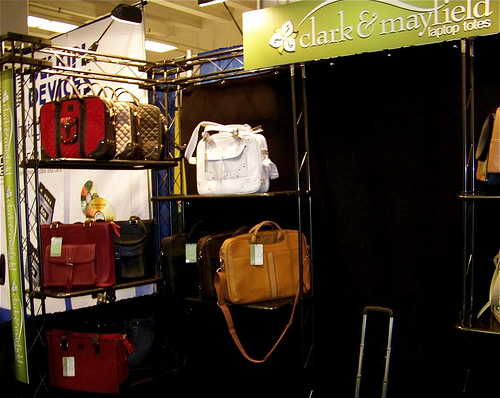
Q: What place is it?
A: It is a store.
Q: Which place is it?
A: It is a store.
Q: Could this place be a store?
A: Yes, it is a store.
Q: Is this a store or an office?
A: It is a store.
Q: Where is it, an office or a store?
A: It is a store.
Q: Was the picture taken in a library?
A: No, the picture was taken in a store.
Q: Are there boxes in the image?
A: No, there are no boxes.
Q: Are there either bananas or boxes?
A: No, there are no boxes or bananas.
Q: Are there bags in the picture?
A: Yes, there is a bag.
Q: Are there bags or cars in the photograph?
A: Yes, there is a bag.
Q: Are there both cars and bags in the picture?
A: No, there is a bag but no cars.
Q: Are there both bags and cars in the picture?
A: No, there is a bag but no cars.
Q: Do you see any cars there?
A: No, there are no cars.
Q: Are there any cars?
A: No, there are no cars.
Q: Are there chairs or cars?
A: No, there are no cars or chairs.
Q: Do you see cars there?
A: No, there are no cars.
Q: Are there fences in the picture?
A: No, there are no fences.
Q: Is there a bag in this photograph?
A: Yes, there is a bag.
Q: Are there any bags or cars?
A: Yes, there is a bag.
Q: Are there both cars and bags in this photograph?
A: No, there is a bag but no cars.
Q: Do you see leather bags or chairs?
A: Yes, there is a leather bag.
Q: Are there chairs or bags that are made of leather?
A: Yes, the bag is made of leather.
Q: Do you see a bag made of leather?
A: Yes, there is a bag that is made of leather.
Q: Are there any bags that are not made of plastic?
A: Yes, there is a bag that is made of leather.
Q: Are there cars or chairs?
A: No, there are no cars or chairs.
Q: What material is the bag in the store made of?
A: The bag is made of leather.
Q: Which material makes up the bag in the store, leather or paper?
A: The bag is made of leather.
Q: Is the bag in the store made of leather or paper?
A: The bag is made of leather.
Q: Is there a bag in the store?
A: Yes, there is a bag in the store.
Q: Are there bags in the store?
A: Yes, there is a bag in the store.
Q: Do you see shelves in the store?
A: No, there is a bag in the store.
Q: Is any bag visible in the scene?
A: Yes, there is a bag.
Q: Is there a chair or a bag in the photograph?
A: Yes, there is a bag.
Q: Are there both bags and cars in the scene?
A: No, there is a bag but no cars.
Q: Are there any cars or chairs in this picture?
A: No, there are no chairs or cars.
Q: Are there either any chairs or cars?
A: No, there are no chairs or cars.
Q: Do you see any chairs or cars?
A: No, there are no chairs or cars.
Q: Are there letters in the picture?
A: Yes, there are letters.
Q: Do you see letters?
A: Yes, there are letters.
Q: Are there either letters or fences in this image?
A: Yes, there are letters.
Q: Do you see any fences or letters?
A: Yes, there are letters.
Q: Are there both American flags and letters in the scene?
A: No, there are letters but no American flags.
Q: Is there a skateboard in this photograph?
A: No, there are no skateboards.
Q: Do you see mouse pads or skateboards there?
A: No, there are no skateboards or mouse pads.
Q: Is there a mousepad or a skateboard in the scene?
A: No, there are no skateboards or mouse pads.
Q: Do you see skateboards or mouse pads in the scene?
A: No, there are no skateboards or mouse pads.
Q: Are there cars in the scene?
A: No, there are no cars.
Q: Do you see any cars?
A: No, there are no cars.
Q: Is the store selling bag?
A: Yes, the store is selling bag.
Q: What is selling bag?
A: The store is selling bag.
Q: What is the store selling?
A: The store is selling bag.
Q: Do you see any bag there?
A: Yes, there is a bag.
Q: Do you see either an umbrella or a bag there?
A: Yes, there is a bag.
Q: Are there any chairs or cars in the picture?
A: No, there are no cars or chairs.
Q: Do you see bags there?
A: Yes, there is a bag.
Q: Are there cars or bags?
A: Yes, there is a bag.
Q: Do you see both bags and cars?
A: No, there is a bag but no cars.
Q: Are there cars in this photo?
A: No, there are no cars.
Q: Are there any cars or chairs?
A: No, there are no cars or chairs.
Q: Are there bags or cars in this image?
A: Yes, there is a bag.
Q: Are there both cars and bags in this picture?
A: No, there is a bag but no cars.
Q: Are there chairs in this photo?
A: No, there are no chairs.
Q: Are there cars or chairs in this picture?
A: No, there are no chairs or cars.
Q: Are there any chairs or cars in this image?
A: No, there are no chairs or cars.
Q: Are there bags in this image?
A: Yes, there is a bag.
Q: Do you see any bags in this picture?
A: Yes, there is a bag.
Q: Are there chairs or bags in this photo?
A: Yes, there is a bag.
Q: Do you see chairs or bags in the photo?
A: Yes, there is a bag.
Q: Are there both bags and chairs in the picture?
A: No, there is a bag but no chairs.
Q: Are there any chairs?
A: No, there are no chairs.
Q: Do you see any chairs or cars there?
A: No, there are no chairs or cars.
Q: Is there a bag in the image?
A: Yes, there is a bag.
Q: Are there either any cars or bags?
A: Yes, there is a bag.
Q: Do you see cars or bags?
A: Yes, there is a bag.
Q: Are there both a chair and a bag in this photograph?
A: No, there is a bag but no chairs.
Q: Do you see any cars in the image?
A: No, there are no cars.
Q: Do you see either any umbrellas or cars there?
A: No, there are no cars or umbrellas.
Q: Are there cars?
A: No, there are no cars.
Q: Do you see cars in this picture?
A: No, there are no cars.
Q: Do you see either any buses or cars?
A: No, there are no cars or buses.